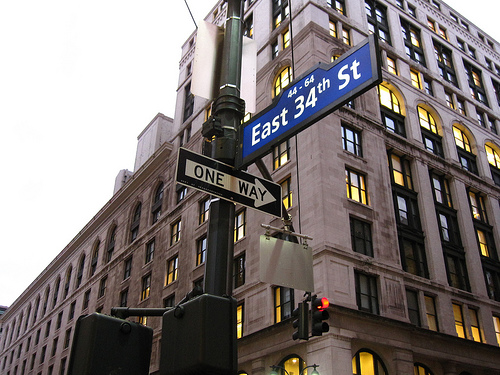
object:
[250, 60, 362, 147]
sign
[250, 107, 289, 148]
word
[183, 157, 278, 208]
arrow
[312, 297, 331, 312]
light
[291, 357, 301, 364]
light